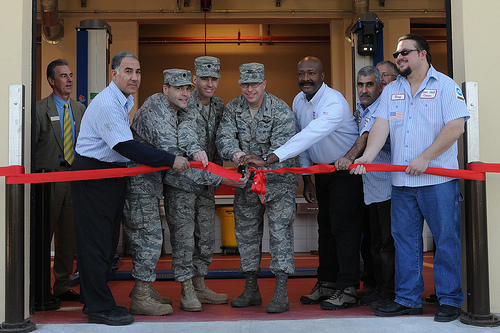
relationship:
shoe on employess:
[433, 303, 466, 325] [348, 34, 470, 322]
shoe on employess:
[370, 304, 415, 318] [348, 34, 470, 322]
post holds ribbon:
[1, 80, 43, 322] [8, 158, 497, 199]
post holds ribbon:
[456, 78, 498, 323] [8, 158, 497, 199]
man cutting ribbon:
[214, 62, 299, 312] [1, 158, 498, 182]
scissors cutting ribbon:
[238, 160, 258, 187] [6, 150, 484, 182]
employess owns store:
[348, 34, 470, 322] [10, 15, 484, 323]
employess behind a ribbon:
[348, 34, 470, 322] [0, 164, 500, 207]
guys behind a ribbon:
[338, 62, 401, 314] [0, 164, 500, 207]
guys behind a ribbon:
[260, 55, 363, 309] [0, 164, 500, 207]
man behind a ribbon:
[214, 62, 299, 312] [0, 164, 500, 207]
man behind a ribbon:
[164, 55, 229, 310] [0, 164, 500, 207]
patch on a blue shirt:
[453, 86, 465, 99] [371, 65, 467, 186]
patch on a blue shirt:
[417, 85, 438, 99] [371, 65, 467, 186]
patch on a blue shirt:
[388, 94, 403, 101] [371, 65, 467, 186]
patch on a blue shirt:
[390, 107, 412, 122] [371, 65, 467, 186]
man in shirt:
[283, 54, 355, 170] [276, 88, 363, 171]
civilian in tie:
[30, 56, 86, 314] [55, 102, 78, 165]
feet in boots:
[263, 291, 286, 316] [131, 270, 291, 316]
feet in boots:
[229, 290, 269, 310] [258, 268, 292, 315]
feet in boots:
[194, 290, 232, 306] [227, 266, 263, 309]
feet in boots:
[178, 293, 201, 313] [196, 277, 228, 306]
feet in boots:
[129, 291, 178, 316] [176, 277, 201, 311]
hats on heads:
[159, 65, 195, 87] [159, 69, 194, 111]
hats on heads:
[190, 52, 222, 79] [192, 55, 221, 98]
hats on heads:
[233, 60, 265, 85] [237, 59, 267, 104]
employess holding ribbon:
[348, 34, 470, 322] [1, 157, 498, 185]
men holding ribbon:
[122, 62, 223, 316] [1, 157, 498, 185]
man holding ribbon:
[214, 62, 299, 312] [1, 157, 498, 185]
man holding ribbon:
[283, 54, 355, 170] [1, 157, 498, 185]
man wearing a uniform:
[214, 62, 299, 312] [214, 95, 297, 273]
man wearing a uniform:
[214, 62, 299, 312] [176, 90, 226, 280]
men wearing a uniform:
[122, 62, 223, 316] [125, 93, 217, 278]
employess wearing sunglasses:
[348, 34, 470, 322] [381, 37, 428, 61]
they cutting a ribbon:
[354, 31, 464, 321] [29, 154, 496, 181]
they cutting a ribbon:
[267, 51, 365, 305] [29, 154, 496, 181]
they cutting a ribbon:
[216, 57, 299, 317] [29, 154, 496, 181]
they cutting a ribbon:
[167, 51, 239, 314] [29, 154, 496, 181]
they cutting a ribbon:
[71, 44, 183, 324] [29, 154, 496, 181]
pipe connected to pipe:
[141, 24, 320, 46] [141, 35, 330, 44]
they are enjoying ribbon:
[30, 36, 471, 285] [1, 161, 498, 193]